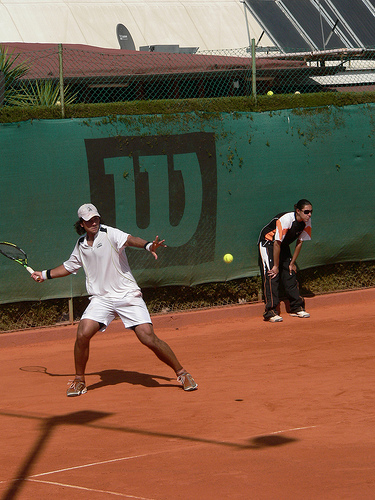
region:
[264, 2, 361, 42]
this is the solar panel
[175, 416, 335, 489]
this is the playground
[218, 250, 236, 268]
this is a tennis ball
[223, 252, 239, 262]
the tennis ball is green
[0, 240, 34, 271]
this is a racket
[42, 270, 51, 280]
this is wristband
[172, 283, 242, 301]
these are grass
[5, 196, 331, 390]
these are players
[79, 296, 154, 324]
this is a white pair of short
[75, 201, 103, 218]
this is the mans cap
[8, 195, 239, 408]
tennis player about to hit ball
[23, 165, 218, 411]
tennis player against a green screen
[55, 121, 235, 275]
large letter on black square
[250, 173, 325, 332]
linesman leaning over near fence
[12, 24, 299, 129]
top of roof behind fence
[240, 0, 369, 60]
elevated grey panels at a slant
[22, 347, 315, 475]
feet away from the base line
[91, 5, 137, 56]
grey satellite dish on roof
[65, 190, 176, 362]
player dressed in tennis whites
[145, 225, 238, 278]
ball close to outstretched hand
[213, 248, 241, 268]
A yellow tennis ball in motion.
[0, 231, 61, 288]
A green and black tennis racket.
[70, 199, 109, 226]
A white hat being worn by the tennis player.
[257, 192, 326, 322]
A woman bending over.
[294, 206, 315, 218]
A pair of black sun glasses worn by the woman.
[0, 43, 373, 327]
A fence for the tennis court.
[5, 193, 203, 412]
A tennis player about to hit a ball.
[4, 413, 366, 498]
White paint on the tennis court.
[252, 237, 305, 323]
Black pants worn by the woman on the tennis court.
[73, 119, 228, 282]
A giant green and black W on the fence.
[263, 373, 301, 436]
part of the ground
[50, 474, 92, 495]
part of a white line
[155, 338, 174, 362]
part of the left leg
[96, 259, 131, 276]
part of a white top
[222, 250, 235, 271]
a round green tennis ball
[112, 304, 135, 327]
part of a white short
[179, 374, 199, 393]
part of a sport shoe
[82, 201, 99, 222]
part of a cap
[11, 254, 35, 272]
part of a racket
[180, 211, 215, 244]
part of a meshed fence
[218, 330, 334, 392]
this is a playing ground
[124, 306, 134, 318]
the man is wearing a short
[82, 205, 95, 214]
the man is wearing a cap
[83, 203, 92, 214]
the cap is white in color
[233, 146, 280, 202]
this is a wall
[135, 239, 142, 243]
the man is light skinned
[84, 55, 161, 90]
this is a fench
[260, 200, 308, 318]
the lady is squrting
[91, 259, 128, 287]
the man is wearing a white T shirt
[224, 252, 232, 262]
this is a ball